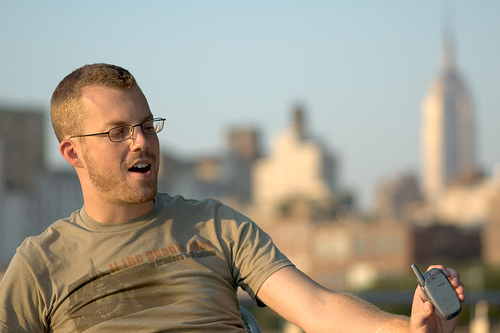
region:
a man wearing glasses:
[1, 56, 455, 331]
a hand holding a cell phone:
[414, 264, 479, 331]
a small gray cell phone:
[412, 265, 463, 320]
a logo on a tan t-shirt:
[62, 242, 219, 319]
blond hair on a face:
[91, 174, 125, 196]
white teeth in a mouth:
[138, 160, 154, 169]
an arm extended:
[271, 268, 376, 330]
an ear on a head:
[54, 137, 91, 171]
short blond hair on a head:
[76, 62, 131, 82]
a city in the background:
[223, 25, 494, 219]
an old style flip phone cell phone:
[398, 260, 468, 317]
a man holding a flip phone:
[5, 50, 474, 330]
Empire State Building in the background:
[405, 7, 493, 199]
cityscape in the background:
[200, 117, 497, 232]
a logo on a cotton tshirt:
[55, 247, 245, 322]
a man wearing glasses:
[39, 73, 183, 205]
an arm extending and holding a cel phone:
[205, 198, 492, 325]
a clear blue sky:
[185, 9, 377, 83]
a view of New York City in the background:
[167, 5, 498, 243]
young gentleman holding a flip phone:
[0, 56, 475, 326]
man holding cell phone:
[15, 65, 456, 332]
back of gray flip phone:
[410, 262, 462, 323]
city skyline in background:
[207, 59, 496, 278]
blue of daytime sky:
[4, 2, 496, 147]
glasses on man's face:
[63, 117, 166, 147]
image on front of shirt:
[58, 237, 219, 325]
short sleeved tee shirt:
[21, 199, 289, 331]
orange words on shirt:
[102, 238, 214, 273]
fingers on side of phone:
[436, 263, 471, 301]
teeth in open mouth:
[128, 157, 157, 175]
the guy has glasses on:
[44, 75, 304, 331]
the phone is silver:
[393, 253, 463, 330]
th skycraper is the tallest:
[396, 58, 484, 189]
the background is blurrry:
[246, 102, 467, 227]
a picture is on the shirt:
[70, 233, 208, 326]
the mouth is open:
[115, 155, 171, 180]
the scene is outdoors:
[6, 26, 493, 318]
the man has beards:
[83, 146, 168, 207]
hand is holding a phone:
[400, 245, 486, 332]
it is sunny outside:
[11, 19, 496, 319]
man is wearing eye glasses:
[57, 110, 172, 152]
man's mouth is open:
[105, 140, 162, 187]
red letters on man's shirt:
[87, 231, 247, 268]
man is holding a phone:
[408, 250, 489, 331]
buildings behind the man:
[176, 1, 497, 231]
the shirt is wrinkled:
[211, 215, 282, 280]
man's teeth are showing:
[123, 152, 153, 175]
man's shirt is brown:
[0, 198, 290, 331]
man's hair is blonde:
[28, 43, 139, 143]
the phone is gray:
[403, 255, 468, 326]